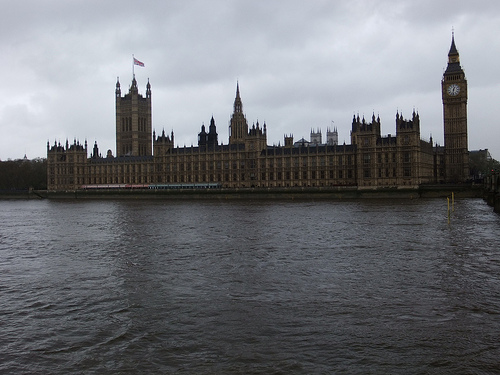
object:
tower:
[215, 71, 272, 151]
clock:
[446, 82, 459, 96]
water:
[210, 222, 429, 323]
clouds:
[1, 0, 380, 47]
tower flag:
[113, 51, 155, 193]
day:
[0, 10, 497, 242]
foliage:
[18, 159, 29, 187]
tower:
[387, 17, 499, 199]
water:
[52, 214, 406, 333]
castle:
[36, 51, 179, 194]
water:
[0, 194, 497, 372]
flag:
[120, 48, 164, 75]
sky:
[1, 2, 333, 53]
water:
[54, 230, 390, 323]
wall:
[188, 126, 266, 161]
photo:
[104, 166, 224, 209]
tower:
[438, 17, 473, 149]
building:
[4, 108, 498, 190]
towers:
[308, 128, 338, 145]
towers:
[348, 106, 423, 192]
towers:
[114, 54, 153, 155]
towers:
[193, 78, 266, 144]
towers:
[45, 131, 89, 194]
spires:
[350, 106, 383, 133]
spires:
[393, 108, 418, 138]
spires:
[308, 127, 320, 143]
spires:
[325, 123, 340, 143]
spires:
[150, 126, 173, 156]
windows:
[263, 166, 354, 185]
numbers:
[447, 84, 458, 100]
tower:
[439, 29, 469, 174]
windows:
[261, 149, 353, 185]